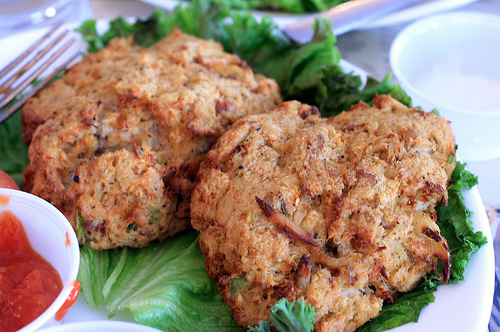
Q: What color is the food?
A: Brown.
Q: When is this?
A: Daytime.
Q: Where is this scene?
A: At a restaurant.